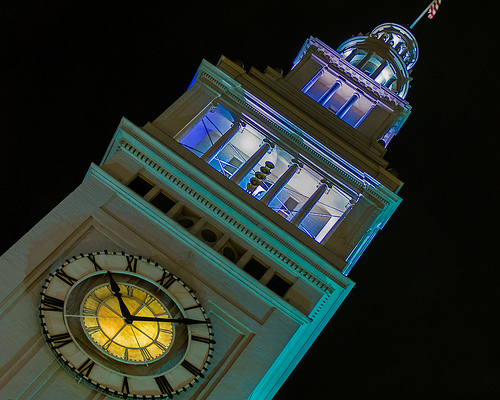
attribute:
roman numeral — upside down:
[74, 355, 97, 377]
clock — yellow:
[38, 247, 213, 390]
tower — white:
[2, 0, 493, 389]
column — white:
[198, 116, 248, 164]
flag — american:
[403, 0, 444, 29]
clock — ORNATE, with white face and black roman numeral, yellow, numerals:
[27, 250, 230, 397]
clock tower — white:
[0, 0, 464, 399]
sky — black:
[6, 20, 491, 396]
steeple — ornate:
[116, 54, 401, 359]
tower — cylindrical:
[0, 17, 421, 397]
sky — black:
[417, 87, 484, 189]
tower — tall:
[0, 66, 432, 398]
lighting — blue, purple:
[186, 31, 403, 235]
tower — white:
[84, 32, 448, 321]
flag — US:
[398, 0, 451, 33]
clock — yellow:
[31, 230, 240, 399]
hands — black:
[102, 267, 216, 339]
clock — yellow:
[103, 268, 163, 358]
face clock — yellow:
[21, 231, 239, 397]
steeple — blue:
[402, 4, 432, 37]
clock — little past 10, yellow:
[34, 241, 223, 399]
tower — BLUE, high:
[2, 0, 447, 398]